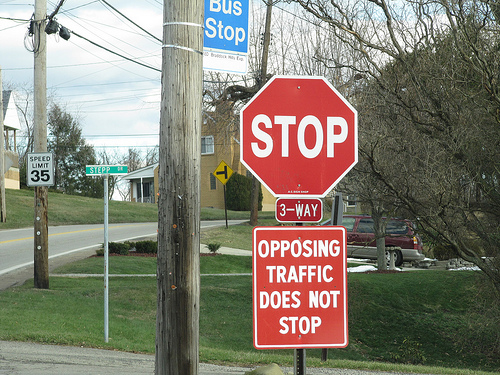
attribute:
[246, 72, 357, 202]
sign — red, white, stop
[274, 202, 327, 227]
sign — red, white, 3 way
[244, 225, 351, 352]
sign — red, traffic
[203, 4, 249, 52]
sign — blue, white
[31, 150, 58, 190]
sign — white, black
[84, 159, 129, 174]
sign — green, white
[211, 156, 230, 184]
sign — yellow, black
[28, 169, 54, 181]
number — 35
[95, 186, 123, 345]
post — metal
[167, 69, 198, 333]
pole — wooden, gray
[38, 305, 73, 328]
grass — green, short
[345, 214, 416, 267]
suv — burdungy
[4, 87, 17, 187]
building — white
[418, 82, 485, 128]
tree — green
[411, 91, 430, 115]
branch — brown